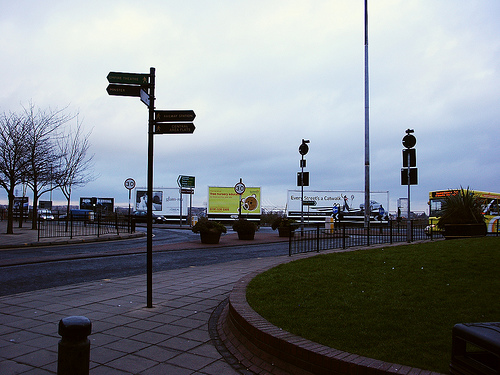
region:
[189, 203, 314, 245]
Plants on the median of raod.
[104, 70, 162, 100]
Street signs on the pole.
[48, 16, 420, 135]
Clouds in the sky.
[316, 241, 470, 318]
The grass is green.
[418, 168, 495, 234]
A bus on the road.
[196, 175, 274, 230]
Advertisement on the sign.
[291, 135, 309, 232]
Three signs on the pole.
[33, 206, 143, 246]
A gate around the sidewalk.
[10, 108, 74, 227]
The trees are bare.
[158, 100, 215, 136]
Two street signs on the pole.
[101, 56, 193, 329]
a city sign post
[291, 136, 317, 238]
a city sign post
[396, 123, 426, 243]
a city sign post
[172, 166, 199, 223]
a city sign post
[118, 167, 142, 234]
a city sign post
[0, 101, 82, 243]
three deciduous trees with no foliage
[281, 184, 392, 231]
a city street billboard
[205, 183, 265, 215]
a city street billboard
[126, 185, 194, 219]
a city street billboard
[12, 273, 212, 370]
a paving stone sidewalk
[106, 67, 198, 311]
a street sign on the walkway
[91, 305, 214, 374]
a stone paver walkway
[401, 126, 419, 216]
a street sign and direction sign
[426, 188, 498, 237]
a yellow city bus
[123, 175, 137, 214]
a speed limit traffic sign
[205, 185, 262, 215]
an advertising billboard along the street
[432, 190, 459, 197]
the bus route display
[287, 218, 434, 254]
a metal fence along the park square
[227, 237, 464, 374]
a round brick wall in the square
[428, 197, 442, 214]
the front windshield of the city bus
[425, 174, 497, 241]
a yellow bus on the road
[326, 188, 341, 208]
a white billboard across the street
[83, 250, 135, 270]
a black cemented road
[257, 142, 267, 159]
a white and blue sky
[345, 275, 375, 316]
a green grass on the ground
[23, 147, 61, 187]
a tree with dry leaves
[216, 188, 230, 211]
a yellow billboard across the street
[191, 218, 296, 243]
flowers beside the road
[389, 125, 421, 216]
signals beside the road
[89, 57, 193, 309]
this is a light post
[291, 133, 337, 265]
this is a light post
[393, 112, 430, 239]
this is a light post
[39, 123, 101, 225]
this is a tree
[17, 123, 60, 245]
this is a tree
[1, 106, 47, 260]
this is a tree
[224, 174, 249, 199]
this is a sign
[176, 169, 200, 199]
this is a sign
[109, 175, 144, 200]
this is a sign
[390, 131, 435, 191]
this is a sign